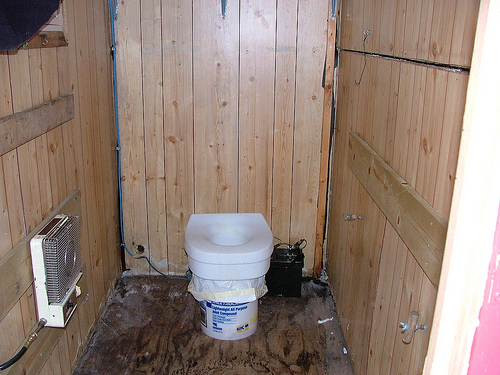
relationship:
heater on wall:
[30, 212, 85, 329] [111, 2, 338, 288]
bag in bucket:
[185, 272, 271, 303] [199, 301, 256, 340]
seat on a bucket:
[182, 213, 275, 262] [199, 301, 256, 340]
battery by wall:
[265, 249, 303, 298] [111, 2, 338, 288]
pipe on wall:
[335, 47, 470, 74] [111, 2, 338, 288]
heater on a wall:
[30, 212, 85, 329] [111, 2, 338, 288]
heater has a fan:
[30, 212, 85, 329] [64, 239, 77, 275]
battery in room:
[265, 249, 303, 298] [1, 2, 500, 375]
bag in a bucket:
[185, 272, 271, 303] [199, 301, 256, 340]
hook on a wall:
[351, 34, 370, 89] [111, 2, 338, 288]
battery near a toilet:
[265, 249, 303, 298] [186, 212, 273, 343]